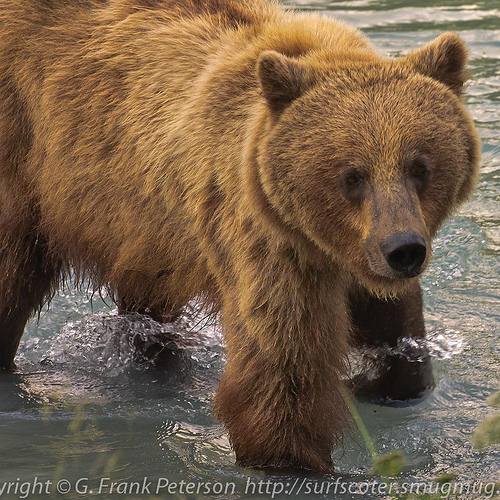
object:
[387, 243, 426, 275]
nose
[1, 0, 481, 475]
bear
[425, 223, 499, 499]
water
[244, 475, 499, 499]
website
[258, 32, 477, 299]
head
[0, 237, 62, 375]
legs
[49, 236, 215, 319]
belly hair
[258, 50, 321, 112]
ear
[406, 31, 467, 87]
ear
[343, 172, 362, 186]
eye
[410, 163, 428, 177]
eye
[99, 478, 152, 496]
frank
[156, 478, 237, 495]
peterson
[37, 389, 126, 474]
grass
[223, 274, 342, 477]
arm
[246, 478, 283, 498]
http